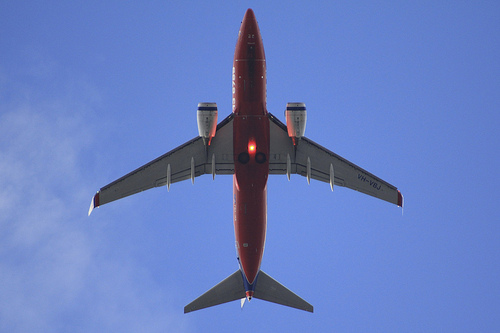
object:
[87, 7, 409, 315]
plane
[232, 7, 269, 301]
body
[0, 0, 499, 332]
sky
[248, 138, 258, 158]
light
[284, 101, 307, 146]
engine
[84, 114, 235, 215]
wing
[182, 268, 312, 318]
tail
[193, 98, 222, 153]
engine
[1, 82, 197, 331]
cloud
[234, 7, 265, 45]
nose